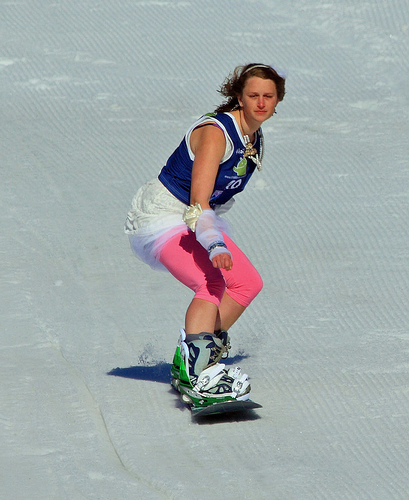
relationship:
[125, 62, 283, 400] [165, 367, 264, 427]
woman on snowboard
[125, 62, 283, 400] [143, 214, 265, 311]
woman wearing leggings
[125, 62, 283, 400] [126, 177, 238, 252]
woman wearing a skirt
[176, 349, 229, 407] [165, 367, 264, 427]
bindings on snowboard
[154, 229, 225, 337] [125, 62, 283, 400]
leg of a woman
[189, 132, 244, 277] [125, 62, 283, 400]
arm of a woman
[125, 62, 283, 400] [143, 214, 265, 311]
woman in leggings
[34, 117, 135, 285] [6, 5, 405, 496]
tracks in snow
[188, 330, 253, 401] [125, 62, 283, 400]
boot on woman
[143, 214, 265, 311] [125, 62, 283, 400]
leggings on woman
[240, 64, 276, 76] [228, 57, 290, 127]
headband on head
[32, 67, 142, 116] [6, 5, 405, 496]
foot prints on snow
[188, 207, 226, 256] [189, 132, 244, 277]
white on arm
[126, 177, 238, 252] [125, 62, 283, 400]
skirt on woman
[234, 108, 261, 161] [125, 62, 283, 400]
necklace on woman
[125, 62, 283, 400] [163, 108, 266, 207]
woman wearing shirt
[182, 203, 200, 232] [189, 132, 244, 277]
bow on arm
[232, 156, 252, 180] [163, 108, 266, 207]
character on shirt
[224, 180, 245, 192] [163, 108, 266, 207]
number on shirt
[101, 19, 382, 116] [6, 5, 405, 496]
lines on snow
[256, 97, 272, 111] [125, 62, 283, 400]
nose on woman